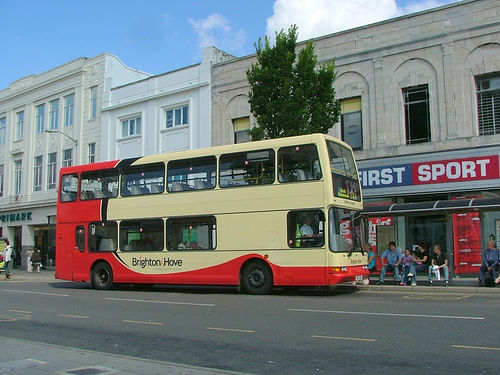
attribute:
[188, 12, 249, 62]
cloud — white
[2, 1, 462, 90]
sky — blue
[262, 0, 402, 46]
cloud — white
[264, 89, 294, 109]
leaf — green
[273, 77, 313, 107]
leaf — green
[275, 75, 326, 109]
leaf — green